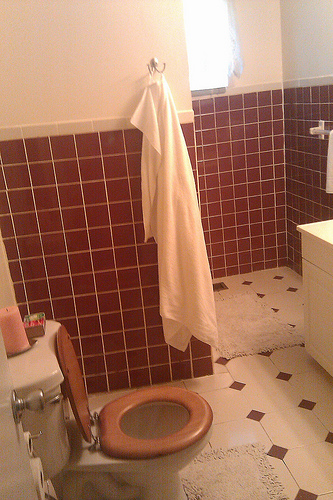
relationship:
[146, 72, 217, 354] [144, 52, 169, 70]
white towel on hook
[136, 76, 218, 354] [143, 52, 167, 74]
white towel on rack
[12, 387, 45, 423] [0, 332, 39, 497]
doorknob on door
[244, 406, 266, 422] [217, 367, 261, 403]
diamond on tile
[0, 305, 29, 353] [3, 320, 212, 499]
candle on toilet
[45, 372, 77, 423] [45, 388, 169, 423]
toilet handle for flushing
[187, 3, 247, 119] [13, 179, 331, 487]
window in bathroom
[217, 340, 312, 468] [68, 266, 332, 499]
tiles in tile floor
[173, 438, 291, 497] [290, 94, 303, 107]
rug on ground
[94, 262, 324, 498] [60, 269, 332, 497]
tiles has pattern